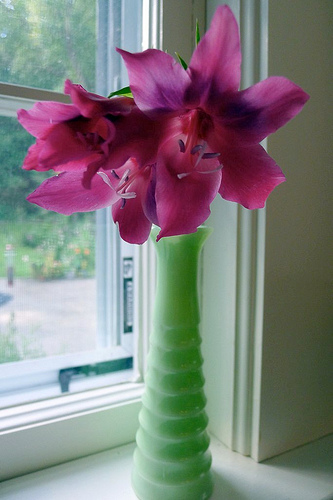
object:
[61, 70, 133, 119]
petals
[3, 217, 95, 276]
lawn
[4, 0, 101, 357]
outside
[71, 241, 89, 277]
flowers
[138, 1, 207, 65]
white trim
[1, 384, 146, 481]
white trim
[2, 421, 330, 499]
window ledge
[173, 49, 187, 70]
leaves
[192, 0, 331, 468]
wall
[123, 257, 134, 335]
sticker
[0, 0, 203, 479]
window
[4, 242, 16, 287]
person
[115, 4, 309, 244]
flower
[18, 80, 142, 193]
flower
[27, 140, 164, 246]
flower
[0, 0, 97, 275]
tree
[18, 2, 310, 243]
pink flowers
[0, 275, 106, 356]
sidewalk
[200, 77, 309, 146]
petal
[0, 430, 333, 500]
counter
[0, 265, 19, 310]
statue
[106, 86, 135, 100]
leaves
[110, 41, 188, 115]
petals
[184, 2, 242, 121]
petals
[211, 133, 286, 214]
petals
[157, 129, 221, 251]
petals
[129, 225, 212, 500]
glass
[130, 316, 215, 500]
ripples